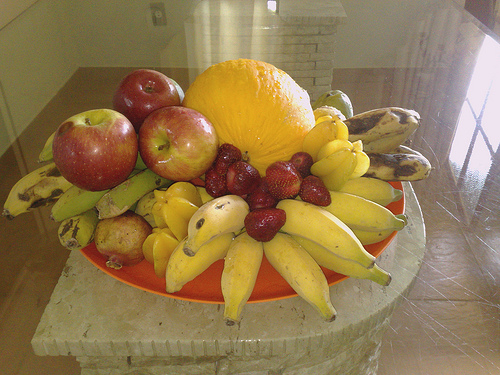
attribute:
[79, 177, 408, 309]
dish — orange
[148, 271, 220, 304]
platter — orange 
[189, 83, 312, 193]
orange — large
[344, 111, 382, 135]
mark — large, black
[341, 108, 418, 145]
fruit — yellow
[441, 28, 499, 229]
windows — glass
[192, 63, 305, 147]
fruit — large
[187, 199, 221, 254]
spot — brown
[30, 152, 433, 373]
table — White 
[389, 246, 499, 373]
tiles — Brown 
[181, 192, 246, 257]
banana — yellow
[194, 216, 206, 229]
mark — black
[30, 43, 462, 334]
bananas — yellow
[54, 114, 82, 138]
spot — brown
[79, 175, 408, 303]
plate — large, orange